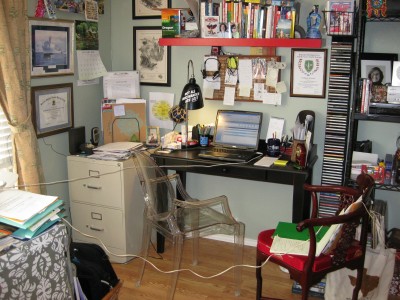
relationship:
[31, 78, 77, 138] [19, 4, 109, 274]
diploma hanging on wall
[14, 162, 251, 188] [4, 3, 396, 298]
cable hanging on room